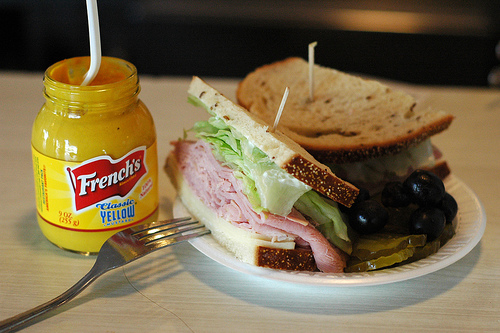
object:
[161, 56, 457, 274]
sandwich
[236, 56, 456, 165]
bread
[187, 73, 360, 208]
bread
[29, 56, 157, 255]
mustard jar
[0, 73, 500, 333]
table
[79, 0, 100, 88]
utensil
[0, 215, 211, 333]
fork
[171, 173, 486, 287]
paper plate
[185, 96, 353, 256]
lettuce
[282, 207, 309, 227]
cheese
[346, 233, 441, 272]
pickles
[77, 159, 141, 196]
french's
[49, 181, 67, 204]
classic yellow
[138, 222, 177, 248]
light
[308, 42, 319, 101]
toothpick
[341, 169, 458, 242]
black olives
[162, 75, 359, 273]
sandwich half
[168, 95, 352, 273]
lettuce and ham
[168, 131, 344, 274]
ham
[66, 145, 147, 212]
flag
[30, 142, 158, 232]
label